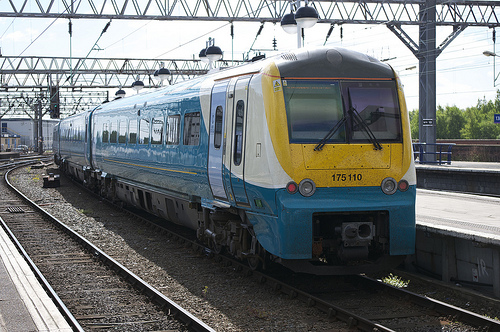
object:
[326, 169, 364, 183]
175110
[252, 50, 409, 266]
front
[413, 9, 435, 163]
pole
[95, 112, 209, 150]
windows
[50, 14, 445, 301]
locomotive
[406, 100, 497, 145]
trees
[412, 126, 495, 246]
platform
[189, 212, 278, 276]
wheels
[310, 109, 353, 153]
wiper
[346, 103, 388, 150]
wiper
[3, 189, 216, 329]
rail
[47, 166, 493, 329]
shade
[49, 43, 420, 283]
passenger train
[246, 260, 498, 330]
railway track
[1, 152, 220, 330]
railway track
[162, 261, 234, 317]
ground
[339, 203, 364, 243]
metal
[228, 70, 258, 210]
door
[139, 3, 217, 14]
bridge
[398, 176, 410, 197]
light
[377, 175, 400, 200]
light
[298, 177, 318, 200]
light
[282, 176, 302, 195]
light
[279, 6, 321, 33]
light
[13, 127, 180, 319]
rails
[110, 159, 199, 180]
strip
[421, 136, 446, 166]
bench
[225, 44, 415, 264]
cabin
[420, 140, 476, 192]
railway